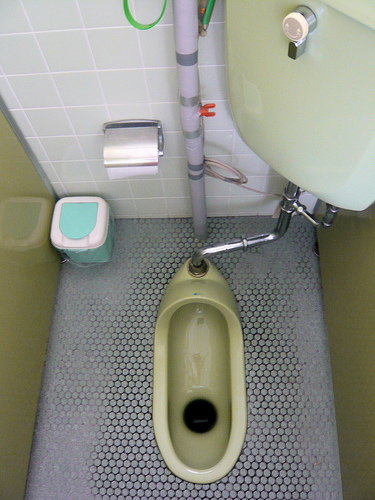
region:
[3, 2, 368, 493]
A bathroom from japan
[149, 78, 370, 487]
this is a squat toilet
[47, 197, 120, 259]
This is a trashcan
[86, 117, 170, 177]
This is a toilet roll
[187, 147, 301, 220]
This is a copper line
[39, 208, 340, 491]
The tiled floor of the bathroom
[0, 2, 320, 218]
The tiled walls of the bathroom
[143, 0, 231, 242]
The pipe that brings water to the bathroom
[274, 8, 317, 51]
A smiley face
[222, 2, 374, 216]
The top of the toilet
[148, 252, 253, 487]
Eastern style toilet in restroom.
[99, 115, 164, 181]
Metal toilet paper holder with silver stand.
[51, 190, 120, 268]
Teal and white flip lid trashcan.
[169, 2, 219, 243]
Long gray pipe with red knob.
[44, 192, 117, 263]
Small trashcan in rather spacious restroom stall.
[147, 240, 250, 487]
Floor style toilet seat in middle of stall.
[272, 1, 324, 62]
Silver lever with pink cap on porcelin basin.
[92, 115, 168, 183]
Toilet paper hung on a metallic service holder.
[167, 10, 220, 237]
Red lever attatched to a long grey pipe.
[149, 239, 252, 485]
Toilet in the middle of a rather spacious restroom.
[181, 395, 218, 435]
hole that the urine is aimed into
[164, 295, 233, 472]
hole that people squat over in asia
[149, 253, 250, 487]
vanilla colored toilet in the ground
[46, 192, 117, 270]
white and aqua plastic waste receptacle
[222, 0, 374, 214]
tank that holds the water for the latrine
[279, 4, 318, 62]
flusher for the floor latrine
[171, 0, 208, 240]
pipe that takes away the waste from the bowl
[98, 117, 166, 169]
stainless steel toilet paper protector and holder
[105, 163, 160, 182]
square of toilet paper hanging out of the dispenser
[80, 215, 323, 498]
dirty section of the octagonal floor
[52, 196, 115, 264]
Teal and white wastebin.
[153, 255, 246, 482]
Squat toilet.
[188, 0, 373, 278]
Tank for a squat toilet.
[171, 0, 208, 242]
A pipe coming from the floor.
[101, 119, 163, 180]
A toilet paper dispenser.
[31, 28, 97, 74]
A white tile in the wall.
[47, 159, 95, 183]
A white tile in the wall.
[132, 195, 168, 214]
A white tile in the wall.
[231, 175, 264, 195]
A white tile in the wall.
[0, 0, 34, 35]
A white tile in the wall.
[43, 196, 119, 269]
Small green and white trash can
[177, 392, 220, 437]
Hole in the floor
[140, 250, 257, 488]
Yellow toilet on the ground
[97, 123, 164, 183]
Roll of toilet paper in metal holder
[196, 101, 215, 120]
Red fixture on the metal pipe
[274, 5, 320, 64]
Silver and white handle on the toilet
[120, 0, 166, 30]
Green cord hanging down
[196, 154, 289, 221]
Cord connecting the pipe and the toilet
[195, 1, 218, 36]
Green fixture on the side of the pipe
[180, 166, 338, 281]
Bright silver pipe on the toilet